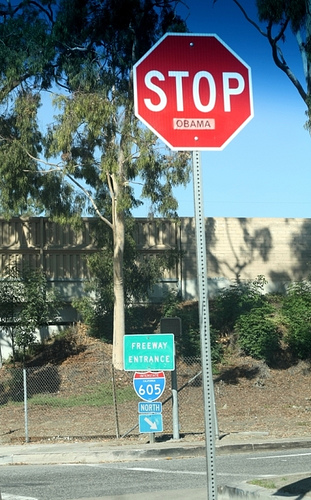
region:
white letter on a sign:
[142, 65, 169, 114]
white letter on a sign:
[167, 66, 192, 115]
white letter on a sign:
[190, 67, 217, 116]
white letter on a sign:
[219, 68, 246, 119]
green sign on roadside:
[121, 331, 178, 373]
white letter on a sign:
[138, 381, 146, 396]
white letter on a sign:
[145, 382, 152, 396]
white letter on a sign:
[153, 382, 160, 396]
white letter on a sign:
[160, 339, 168, 349]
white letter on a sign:
[163, 353, 170, 363]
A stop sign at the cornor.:
[146, 33, 243, 413]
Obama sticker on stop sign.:
[169, 114, 236, 136]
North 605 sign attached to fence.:
[129, 372, 173, 435]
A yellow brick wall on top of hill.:
[211, 219, 302, 278]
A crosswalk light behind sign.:
[156, 314, 184, 336]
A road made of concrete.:
[154, 459, 273, 476]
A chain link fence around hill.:
[15, 369, 122, 430]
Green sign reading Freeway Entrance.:
[123, 336, 178, 371]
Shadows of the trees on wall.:
[217, 220, 289, 279]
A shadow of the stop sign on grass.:
[261, 472, 308, 498]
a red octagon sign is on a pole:
[131, 30, 255, 207]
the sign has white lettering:
[130, 30, 256, 157]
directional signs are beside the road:
[121, 332, 175, 435]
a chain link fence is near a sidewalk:
[4, 360, 307, 435]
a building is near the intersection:
[3, 208, 309, 408]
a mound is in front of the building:
[12, 294, 307, 432]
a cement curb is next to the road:
[5, 436, 307, 460]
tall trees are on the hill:
[9, 11, 310, 405]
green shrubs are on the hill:
[87, 277, 309, 371]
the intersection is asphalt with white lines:
[5, 456, 304, 495]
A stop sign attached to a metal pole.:
[132, 32, 254, 498]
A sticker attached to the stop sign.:
[173, 117, 214, 129]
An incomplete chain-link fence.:
[1, 356, 203, 442]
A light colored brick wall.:
[180, 216, 309, 299]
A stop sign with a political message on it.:
[132, 33, 254, 150]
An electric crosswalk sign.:
[159, 316, 181, 440]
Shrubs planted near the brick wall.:
[162, 273, 309, 374]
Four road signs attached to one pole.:
[123, 333, 174, 443]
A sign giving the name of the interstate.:
[132, 370, 165, 399]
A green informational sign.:
[122, 333, 173, 371]